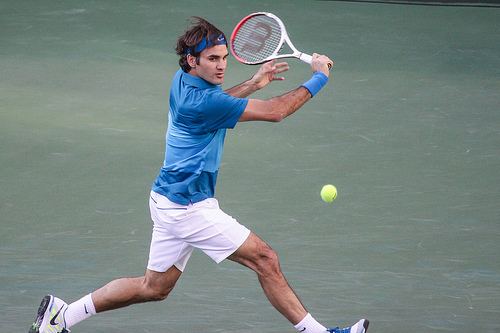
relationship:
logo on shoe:
[48, 302, 64, 325] [30, 295, 67, 332]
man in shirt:
[23, 10, 369, 332] [151, 68, 250, 204]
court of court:
[0, 1, 496, 332] [0, 1, 496, 332]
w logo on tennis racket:
[238, 22, 272, 56] [232, 10, 316, 66]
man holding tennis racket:
[23, 10, 369, 332] [232, 10, 316, 66]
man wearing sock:
[23, 10, 369, 332] [66, 294, 96, 330]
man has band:
[23, 10, 369, 332] [300, 71, 332, 99]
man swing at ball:
[23, 10, 369, 332] [317, 182, 339, 203]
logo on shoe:
[48, 302, 64, 325] [27, 291, 69, 331]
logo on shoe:
[81, 303, 89, 313] [325, 316, 369, 331]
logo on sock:
[298, 327, 308, 332] [293, 311, 325, 331]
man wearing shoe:
[23, 10, 369, 332] [27, 291, 69, 331]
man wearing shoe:
[23, 10, 369, 332] [325, 316, 369, 331]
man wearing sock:
[23, 10, 369, 332] [293, 311, 325, 331]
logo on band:
[209, 34, 223, 41] [188, 36, 226, 53]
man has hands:
[23, 10, 369, 332] [238, 46, 283, 81]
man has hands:
[23, 10, 369, 332] [294, 44, 369, 123]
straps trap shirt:
[142, 112, 232, 178] [150, 69, 249, 204]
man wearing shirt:
[23, 10, 369, 332] [151, 68, 250, 204]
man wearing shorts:
[23, 10, 369, 332] [147, 189, 252, 273]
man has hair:
[23, 10, 369, 332] [175, 15, 227, 73]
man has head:
[23, 10, 369, 332] [177, 14, 231, 84]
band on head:
[188, 36, 226, 53] [177, 14, 231, 84]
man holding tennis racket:
[23, 10, 369, 332] [228, 0, 332, 70]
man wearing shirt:
[59, 10, 369, 321] [154, 92, 251, 207]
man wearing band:
[23, 10, 369, 332] [188, 36, 226, 53]